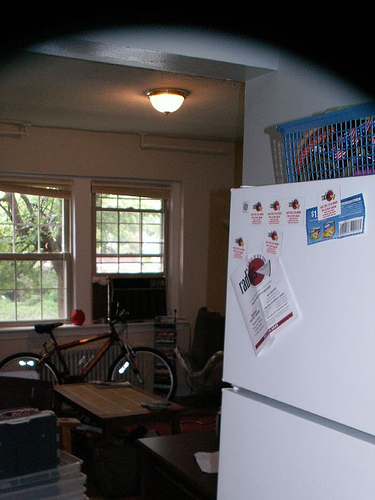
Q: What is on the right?
A: Refrigerator.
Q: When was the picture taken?
A: Daytime.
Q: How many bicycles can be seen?
A: One.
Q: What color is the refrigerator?
A: White.